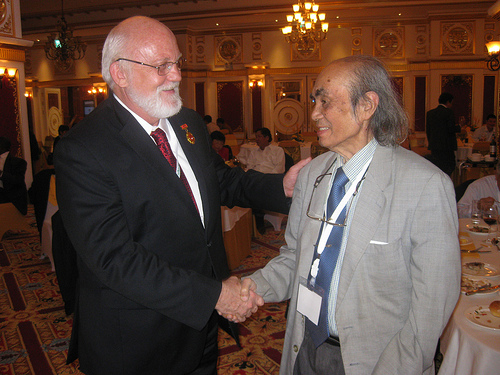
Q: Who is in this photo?
A: Two men.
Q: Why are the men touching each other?
A: They're shaking hands.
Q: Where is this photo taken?
A: At a reception.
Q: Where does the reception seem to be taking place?
A: A banquet hall.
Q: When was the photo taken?
A: After dinner.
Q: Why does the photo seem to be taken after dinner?
A: The plates are empty.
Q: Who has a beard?
A: The man on the left.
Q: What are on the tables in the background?
A: White tablecloths.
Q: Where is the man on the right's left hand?
A: In his pocket.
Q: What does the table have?
A: Food.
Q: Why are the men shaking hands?
A: Meeting.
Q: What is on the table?
A: Plates.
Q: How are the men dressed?
A: In suits.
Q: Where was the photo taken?
A: At a banquet hall.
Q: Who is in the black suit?
A: The man with the beard.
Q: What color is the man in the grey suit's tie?
A: Blue.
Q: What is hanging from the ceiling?
A: Chandeliers.